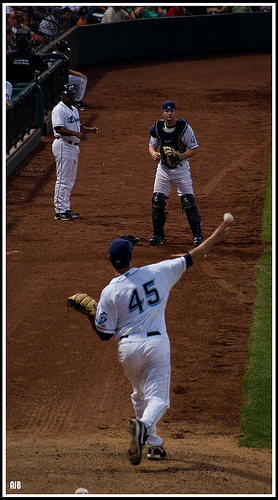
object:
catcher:
[149, 100, 204, 249]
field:
[5, 4, 273, 494]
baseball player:
[66, 217, 232, 467]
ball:
[224, 212, 235, 224]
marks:
[198, 137, 270, 200]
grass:
[240, 160, 271, 448]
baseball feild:
[6, 9, 272, 496]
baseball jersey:
[95, 256, 187, 341]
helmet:
[61, 83, 76, 96]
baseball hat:
[109, 238, 134, 264]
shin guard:
[151, 192, 169, 234]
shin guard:
[180, 193, 202, 235]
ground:
[10, 56, 273, 495]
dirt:
[187, 313, 243, 496]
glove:
[66, 293, 97, 316]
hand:
[212, 219, 231, 242]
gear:
[149, 119, 199, 163]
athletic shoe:
[54, 212, 73, 220]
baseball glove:
[160, 145, 181, 170]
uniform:
[94, 257, 188, 447]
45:
[128, 278, 161, 315]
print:
[127, 278, 160, 315]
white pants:
[51, 136, 80, 214]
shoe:
[128, 418, 150, 466]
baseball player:
[51, 83, 99, 223]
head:
[107, 238, 133, 270]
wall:
[62, 19, 230, 94]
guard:
[152, 192, 167, 233]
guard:
[181, 193, 202, 236]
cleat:
[128, 419, 140, 466]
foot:
[128, 418, 146, 465]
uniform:
[50, 101, 81, 213]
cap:
[162, 100, 176, 111]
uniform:
[148, 116, 201, 238]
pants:
[118, 337, 171, 447]